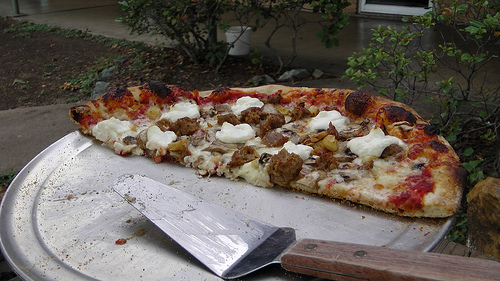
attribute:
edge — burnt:
[345, 88, 418, 126]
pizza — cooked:
[75, 50, 487, 230]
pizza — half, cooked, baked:
[66, 80, 463, 218]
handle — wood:
[286, 229, 498, 276]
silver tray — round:
[9, 129, 309, 279]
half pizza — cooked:
[68, 55, 475, 214]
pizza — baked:
[100, 87, 473, 212]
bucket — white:
[220, 26, 255, 54]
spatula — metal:
[108, 170, 497, 278]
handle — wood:
[285, 236, 499, 279]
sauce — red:
[391, 167, 435, 210]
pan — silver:
[1, 129, 453, 279]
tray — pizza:
[1, 128, 453, 279]